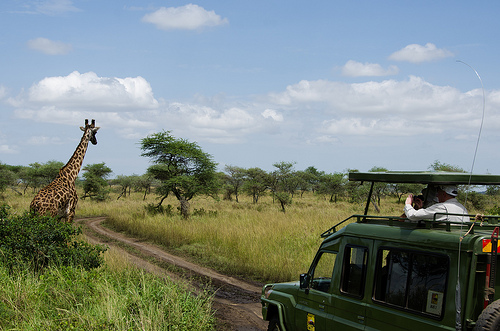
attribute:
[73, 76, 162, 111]
clouds — white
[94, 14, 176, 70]
sky — blue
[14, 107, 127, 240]
giraffe — roadside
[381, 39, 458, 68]
cloud — white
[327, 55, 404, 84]
cloud — white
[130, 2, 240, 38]
cloud — white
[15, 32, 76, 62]
cloud — white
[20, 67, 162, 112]
cloud — white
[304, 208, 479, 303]
vehicle — green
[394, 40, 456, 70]
clouds — white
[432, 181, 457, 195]
hat — white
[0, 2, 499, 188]
sky — blue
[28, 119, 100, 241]
giraffe — wild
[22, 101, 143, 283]
giraffe — adult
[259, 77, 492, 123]
clouds — white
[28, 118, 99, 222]
giraffe — large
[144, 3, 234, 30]
cloud — white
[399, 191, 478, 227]
shirt — white